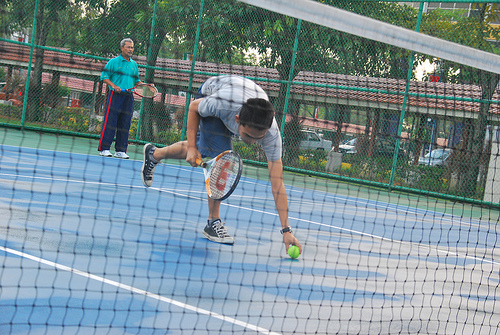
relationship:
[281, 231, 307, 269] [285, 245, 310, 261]
fingers on ball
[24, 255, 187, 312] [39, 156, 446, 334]
line on court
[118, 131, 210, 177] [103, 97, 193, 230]
leg in air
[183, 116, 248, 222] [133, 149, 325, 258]
racket in front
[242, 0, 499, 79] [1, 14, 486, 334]
stripe on net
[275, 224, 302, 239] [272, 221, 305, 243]
watch around wrist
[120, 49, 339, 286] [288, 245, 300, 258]
man playing ball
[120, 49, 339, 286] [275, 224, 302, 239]
man wearing watch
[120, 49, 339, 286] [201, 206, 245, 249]
man wearing shoe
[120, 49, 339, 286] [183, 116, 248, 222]
man holding racket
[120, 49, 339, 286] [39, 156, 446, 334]
man on court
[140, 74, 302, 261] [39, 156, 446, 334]
man on court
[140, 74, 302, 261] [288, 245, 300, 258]
man playing ball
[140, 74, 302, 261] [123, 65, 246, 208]
man holding rackets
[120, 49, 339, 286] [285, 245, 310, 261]
man grabbing ball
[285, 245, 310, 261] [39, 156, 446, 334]
ball on court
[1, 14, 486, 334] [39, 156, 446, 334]
net on court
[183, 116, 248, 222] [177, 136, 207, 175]
racket in hand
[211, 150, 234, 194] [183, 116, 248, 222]
w on racket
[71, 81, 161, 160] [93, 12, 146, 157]
pants on man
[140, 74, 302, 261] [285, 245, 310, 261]
man picking up ball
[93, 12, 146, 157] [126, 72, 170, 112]
man holds racket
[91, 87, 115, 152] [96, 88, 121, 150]
stripe down leg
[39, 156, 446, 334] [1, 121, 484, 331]
lines are on ground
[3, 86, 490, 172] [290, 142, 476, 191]
cars on street